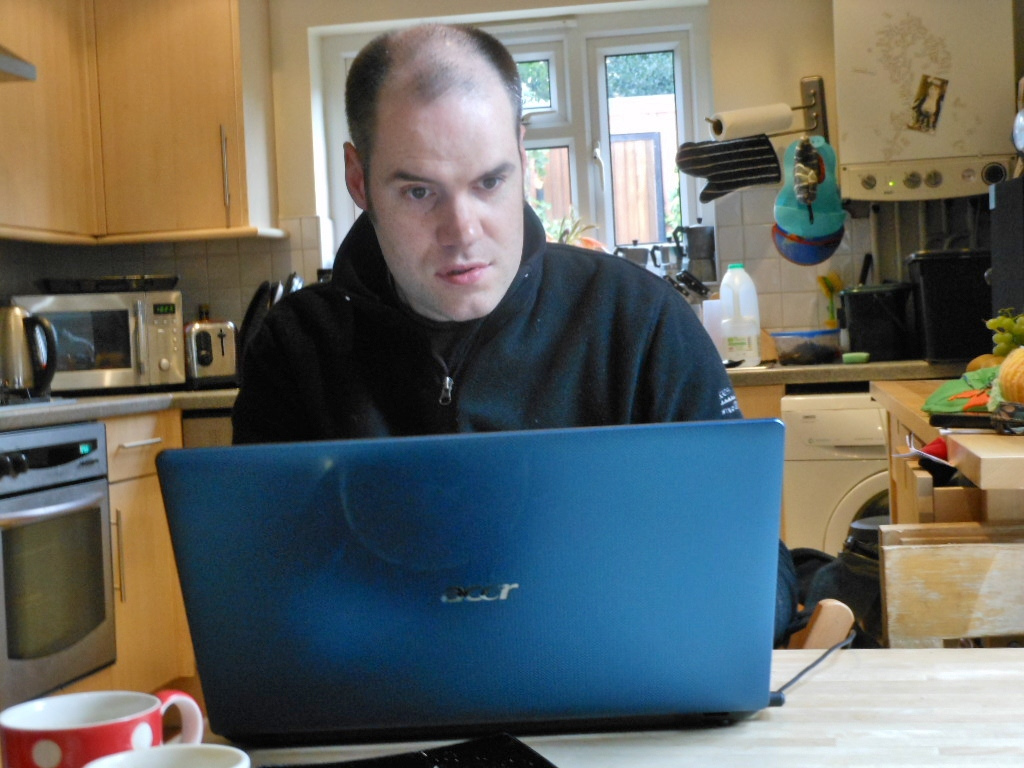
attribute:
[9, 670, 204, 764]
mug — red, white 